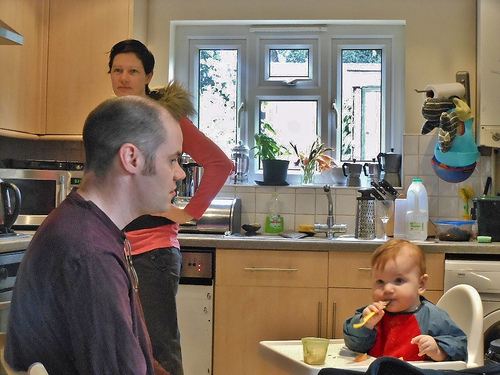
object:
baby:
[339, 235, 473, 363]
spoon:
[353, 300, 389, 329]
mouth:
[379, 297, 398, 303]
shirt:
[340, 299, 471, 363]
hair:
[369, 237, 428, 277]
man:
[0, 91, 190, 375]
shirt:
[0, 183, 157, 374]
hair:
[80, 95, 168, 179]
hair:
[105, 37, 157, 74]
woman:
[105, 37, 237, 374]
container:
[403, 176, 430, 242]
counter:
[182, 237, 499, 255]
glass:
[376, 199, 396, 242]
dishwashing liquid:
[264, 190, 286, 237]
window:
[169, 19, 401, 186]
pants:
[132, 246, 183, 375]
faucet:
[313, 183, 348, 242]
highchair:
[256, 279, 489, 373]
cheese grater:
[354, 187, 376, 241]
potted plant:
[247, 120, 283, 163]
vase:
[299, 165, 316, 186]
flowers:
[289, 136, 340, 173]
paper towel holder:
[412, 70, 472, 108]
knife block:
[385, 192, 442, 237]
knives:
[368, 187, 389, 206]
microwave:
[0, 167, 88, 231]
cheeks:
[398, 285, 416, 305]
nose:
[174, 161, 187, 182]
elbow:
[203, 150, 234, 178]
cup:
[301, 336, 331, 367]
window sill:
[190, 179, 405, 190]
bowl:
[432, 219, 477, 243]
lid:
[433, 220, 476, 227]